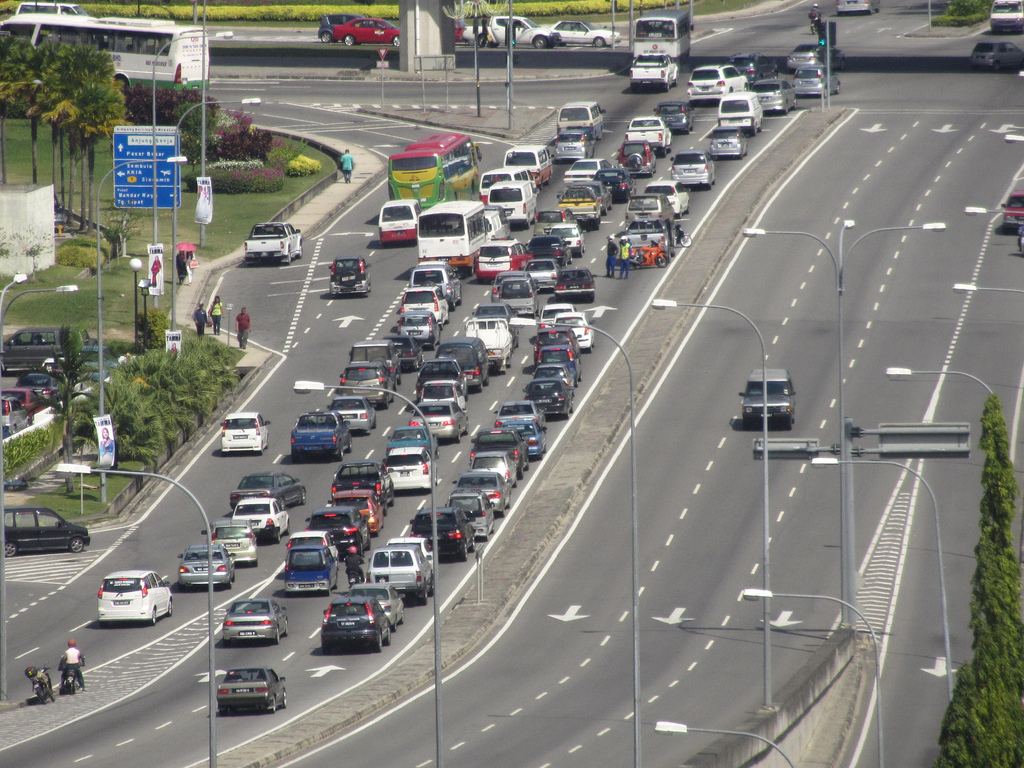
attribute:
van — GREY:
[738, 370, 793, 427]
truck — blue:
[286, 404, 354, 461]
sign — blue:
[115, 126, 185, 206]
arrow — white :
[307, 84, 439, 108]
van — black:
[4, 502, 95, 555]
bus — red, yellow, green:
[384, 128, 484, 211]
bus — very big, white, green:
[6, 9, 214, 100]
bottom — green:
[121, 74, 212, 94]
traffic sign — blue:
[110, 121, 182, 212]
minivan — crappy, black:
[2, 508, 95, 558]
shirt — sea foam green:
[337, 152, 355, 172]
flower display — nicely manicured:
[121, 76, 329, 197]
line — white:
[648, 554, 664, 574]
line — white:
[657, 530, 679, 550]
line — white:
[674, 502, 692, 524]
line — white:
[698, 456, 720, 476]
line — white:
[633, 580, 649, 602]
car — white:
[212, 403, 276, 456]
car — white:
[377, 438, 435, 497]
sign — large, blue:
[102, 110, 192, 211]